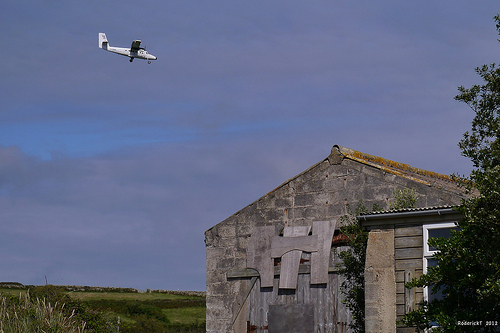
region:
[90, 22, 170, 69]
plane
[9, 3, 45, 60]
white clouds in blue sky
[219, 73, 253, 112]
white clouds in blue sky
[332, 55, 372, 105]
white clouds in blue sky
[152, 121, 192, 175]
white clouds in blue sky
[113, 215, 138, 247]
white clouds in blue sky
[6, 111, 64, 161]
white clouds in blue sky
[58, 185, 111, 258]
white clouds in blue sky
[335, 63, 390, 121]
white clouds in blue sky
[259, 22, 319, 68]
white clouds in blue sky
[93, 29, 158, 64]
a small white plane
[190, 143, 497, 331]
an old farm building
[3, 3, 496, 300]
blue sky with a few clouds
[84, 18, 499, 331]
small plane flying over a building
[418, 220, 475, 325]
window in a building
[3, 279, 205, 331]
green fields in the background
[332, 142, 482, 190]
orange moss on the roof of a building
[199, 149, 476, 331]
grey stone front of a building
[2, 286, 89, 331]
a tall grassy plant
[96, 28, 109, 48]
tail of a small plane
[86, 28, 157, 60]
white airplane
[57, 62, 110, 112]
white clouds in blue sky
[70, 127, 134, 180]
white clouds in blue sky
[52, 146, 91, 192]
white clouds in blue sky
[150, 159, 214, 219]
white clouds in blue sky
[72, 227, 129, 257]
white clouds in blue sky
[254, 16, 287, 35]
white clouds in blue sky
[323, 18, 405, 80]
white clouds in blue sky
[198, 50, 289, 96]
white clouds in blue sky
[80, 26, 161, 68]
whtie plane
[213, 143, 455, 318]
brown and white building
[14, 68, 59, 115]
white clouds in blue sky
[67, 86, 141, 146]
white clouds in blue sky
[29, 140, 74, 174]
white clouds in blue sky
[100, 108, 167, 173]
white clouds in blue sky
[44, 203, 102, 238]
white clouds in blue sky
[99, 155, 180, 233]
white clouds in blue sky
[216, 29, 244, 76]
white clouds in blue sky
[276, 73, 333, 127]
white clouds in blue sky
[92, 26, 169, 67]
white airplane in air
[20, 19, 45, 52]
white clouds in blue sky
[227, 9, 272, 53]
white clouds in blue sky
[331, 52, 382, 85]
white clouds in blue sky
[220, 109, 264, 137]
white clouds in blue sky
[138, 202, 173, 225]
white clouds in blue sky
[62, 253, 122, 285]
white clouds in blue sky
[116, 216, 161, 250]
white clouds in blue sky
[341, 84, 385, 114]
white clouds in blue sky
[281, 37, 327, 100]
white clouds in blue sky